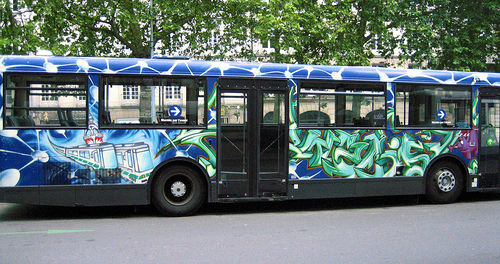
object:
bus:
[1, 56, 500, 217]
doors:
[259, 89, 288, 196]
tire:
[150, 160, 206, 216]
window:
[299, 84, 384, 127]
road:
[0, 198, 500, 264]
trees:
[0, 0, 250, 57]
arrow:
[438, 111, 445, 118]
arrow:
[0, 229, 93, 233]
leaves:
[436, 4, 486, 68]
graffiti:
[290, 129, 475, 180]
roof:
[0, 54, 498, 86]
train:
[46, 136, 117, 168]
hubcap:
[171, 181, 187, 197]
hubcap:
[437, 171, 455, 193]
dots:
[446, 172, 449, 175]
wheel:
[426, 162, 466, 202]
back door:
[218, 87, 253, 197]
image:
[448, 130, 478, 159]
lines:
[42, 163, 45, 185]